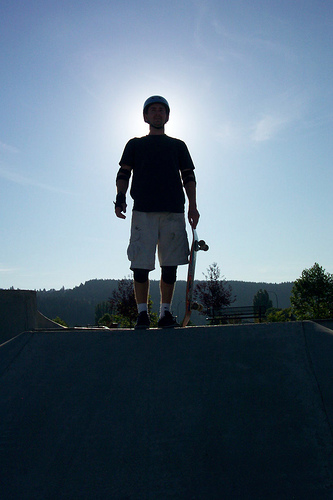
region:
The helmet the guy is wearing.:
[138, 90, 175, 106]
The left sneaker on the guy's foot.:
[128, 309, 152, 325]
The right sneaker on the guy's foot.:
[153, 307, 179, 327]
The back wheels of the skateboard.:
[193, 297, 207, 314]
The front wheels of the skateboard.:
[197, 239, 215, 255]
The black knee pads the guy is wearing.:
[129, 266, 180, 289]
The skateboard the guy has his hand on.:
[176, 213, 202, 331]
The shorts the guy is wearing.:
[131, 205, 189, 271]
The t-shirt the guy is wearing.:
[125, 139, 195, 203]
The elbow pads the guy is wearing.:
[110, 161, 204, 193]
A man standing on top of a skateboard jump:
[101, 75, 212, 343]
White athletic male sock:
[131, 299, 154, 311]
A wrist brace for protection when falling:
[112, 192, 130, 221]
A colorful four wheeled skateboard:
[180, 222, 210, 326]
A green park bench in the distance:
[204, 303, 264, 325]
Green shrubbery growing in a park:
[286, 262, 331, 324]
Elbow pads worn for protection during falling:
[107, 166, 131, 191]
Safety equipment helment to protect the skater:
[134, 92, 176, 106]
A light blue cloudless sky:
[211, 20, 332, 179]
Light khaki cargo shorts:
[125, 208, 192, 277]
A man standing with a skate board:
[114, 89, 211, 345]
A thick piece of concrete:
[1, 316, 319, 486]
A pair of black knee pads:
[125, 251, 187, 290]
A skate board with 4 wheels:
[177, 214, 211, 332]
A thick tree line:
[8, 266, 293, 334]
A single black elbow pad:
[110, 162, 134, 191]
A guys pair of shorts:
[122, 208, 190, 280]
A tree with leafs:
[187, 271, 241, 318]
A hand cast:
[107, 192, 135, 220]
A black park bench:
[194, 301, 282, 327]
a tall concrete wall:
[5, 326, 332, 497]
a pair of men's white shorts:
[128, 208, 189, 267]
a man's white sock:
[136, 300, 148, 313]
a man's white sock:
[157, 302, 170, 313]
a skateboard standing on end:
[181, 226, 210, 330]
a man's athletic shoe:
[134, 312, 149, 330]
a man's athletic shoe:
[156, 314, 175, 326]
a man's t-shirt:
[118, 133, 194, 214]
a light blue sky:
[3, 0, 329, 288]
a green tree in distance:
[291, 263, 332, 325]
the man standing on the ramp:
[107, 88, 218, 325]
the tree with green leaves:
[281, 277, 330, 314]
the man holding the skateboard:
[108, 84, 216, 325]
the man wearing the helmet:
[133, 91, 178, 132]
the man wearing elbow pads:
[113, 131, 201, 199]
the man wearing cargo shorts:
[119, 188, 203, 286]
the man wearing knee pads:
[127, 260, 181, 282]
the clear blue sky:
[10, 7, 90, 70]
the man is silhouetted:
[100, 92, 212, 300]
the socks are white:
[127, 296, 188, 319]